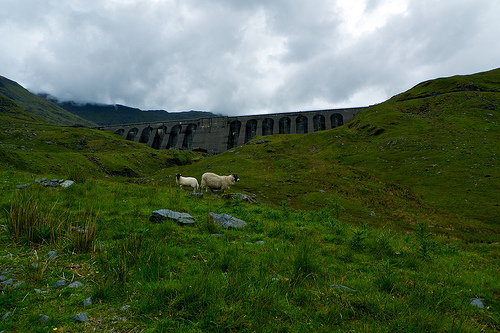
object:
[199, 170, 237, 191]
sheep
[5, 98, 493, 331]
field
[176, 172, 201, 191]
sheep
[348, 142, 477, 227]
grass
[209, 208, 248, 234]
rocks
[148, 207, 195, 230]
rocks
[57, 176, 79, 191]
rocks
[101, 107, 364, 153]
bridge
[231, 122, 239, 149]
arches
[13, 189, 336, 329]
grass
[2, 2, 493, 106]
sky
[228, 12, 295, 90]
clouds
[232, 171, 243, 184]
head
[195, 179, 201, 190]
tail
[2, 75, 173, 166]
hill